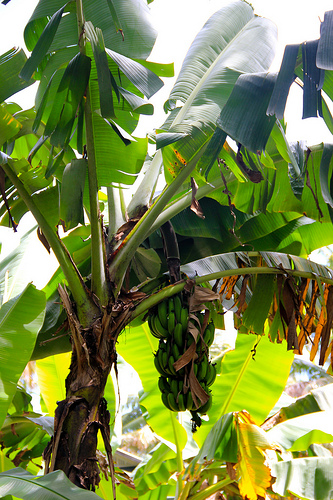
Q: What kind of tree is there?
A: Palm.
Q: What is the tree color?
A: Green.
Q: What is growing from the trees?
A: Bananas.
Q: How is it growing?
A: Hanging.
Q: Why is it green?
A: Not ripe.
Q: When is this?
A: Daytime.